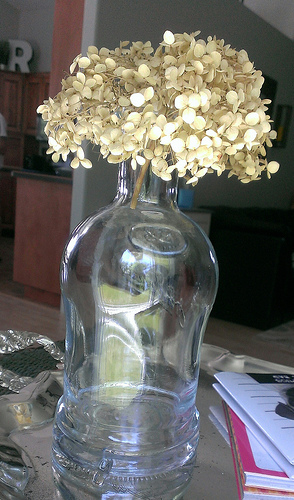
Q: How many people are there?
A: None.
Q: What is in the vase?
A: Flowers.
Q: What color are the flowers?
A: Cream.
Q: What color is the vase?
A: Clear.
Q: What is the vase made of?
A: Glass.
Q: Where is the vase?
A: On the table.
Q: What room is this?
A: Dining room.